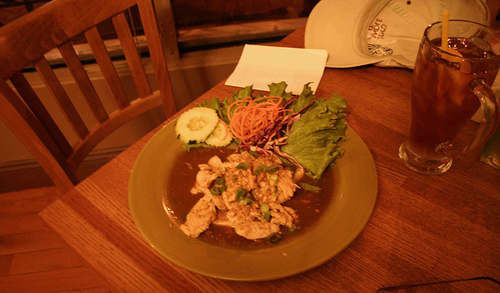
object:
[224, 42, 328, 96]
paper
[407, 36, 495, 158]
tea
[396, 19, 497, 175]
glass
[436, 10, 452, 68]
straw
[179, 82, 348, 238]
food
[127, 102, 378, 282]
plate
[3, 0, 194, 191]
chair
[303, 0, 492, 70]
cap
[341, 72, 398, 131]
table